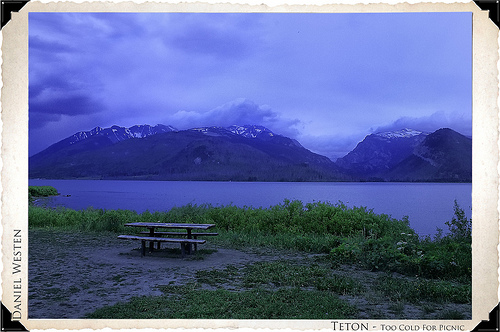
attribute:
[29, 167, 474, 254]
lake — blue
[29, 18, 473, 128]
clouds — white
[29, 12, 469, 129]
sky — blue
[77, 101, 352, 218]
fluffy — huge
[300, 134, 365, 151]
clouds — white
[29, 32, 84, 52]
clouds — white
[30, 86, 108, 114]
clouds — white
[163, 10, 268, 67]
clouds — white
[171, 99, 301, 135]
clouds — white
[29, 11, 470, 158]
sky — blue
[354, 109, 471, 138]
clouds — white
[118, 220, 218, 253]
bench — old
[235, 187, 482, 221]
water — blue, clear, rippled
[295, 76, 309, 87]
clouds — white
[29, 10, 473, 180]
sky — blue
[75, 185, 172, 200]
ripples — blue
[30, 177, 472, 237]
water — clear, blue, rippled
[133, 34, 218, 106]
clouds — white 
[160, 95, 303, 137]
cloud — white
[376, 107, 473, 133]
cloud — white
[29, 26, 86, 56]
cloud — white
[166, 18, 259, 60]
cloud — white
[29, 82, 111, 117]
cloud — white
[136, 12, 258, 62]
clouds — white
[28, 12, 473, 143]
sky — blue, dark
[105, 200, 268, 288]
bench — wooden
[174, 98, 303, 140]
cloud — white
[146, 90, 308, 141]
cloud — white